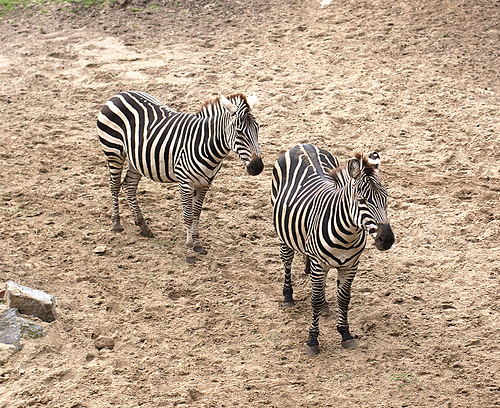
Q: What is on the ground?
A: Sand.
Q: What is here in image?
A: Zebras.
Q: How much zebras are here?
A: Two.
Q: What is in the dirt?
A: Zebras.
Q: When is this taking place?
A: During the day time.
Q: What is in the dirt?
A: Hoof prints.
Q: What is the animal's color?
A: White and black.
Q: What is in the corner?
A: Grass.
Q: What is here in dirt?
A: Zebras.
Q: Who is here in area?
A: Zebras.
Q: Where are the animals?
A: Outside on sand.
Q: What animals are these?
A: Zebras.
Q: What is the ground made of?
A: Sand.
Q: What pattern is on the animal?
A: Stripes.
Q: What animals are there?
A: Zebras.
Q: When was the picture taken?
A: Daytime.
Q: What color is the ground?
A: Brown.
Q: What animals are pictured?
A: Zebra.